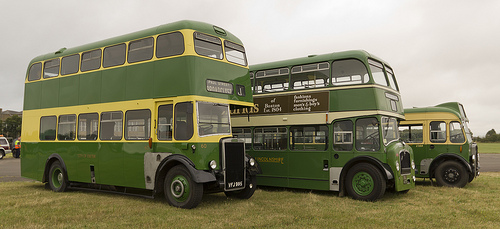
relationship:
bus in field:
[13, 22, 259, 217] [3, 134, 499, 226]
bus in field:
[229, 50, 416, 200] [3, 134, 499, 226]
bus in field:
[399, 101, 478, 188] [3, 134, 499, 226]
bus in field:
[402, 100, 486, 200] [4, 168, 499, 226]